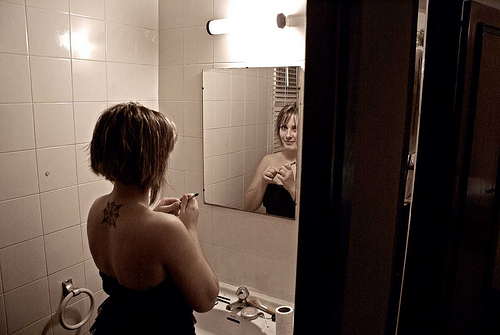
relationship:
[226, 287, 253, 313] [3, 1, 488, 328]
faucet in bathroom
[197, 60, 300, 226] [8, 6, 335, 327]
mirror in bathroom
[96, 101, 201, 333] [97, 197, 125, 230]
lady has tattoo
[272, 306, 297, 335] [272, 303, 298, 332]
tissue has roll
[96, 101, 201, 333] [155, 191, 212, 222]
lady has hands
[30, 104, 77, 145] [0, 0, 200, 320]
tile on wall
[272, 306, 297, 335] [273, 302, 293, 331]
tissue has roll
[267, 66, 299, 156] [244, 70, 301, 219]
window has reflection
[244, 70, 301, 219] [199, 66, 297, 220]
reflection in mirror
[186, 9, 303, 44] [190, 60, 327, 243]
light over mirror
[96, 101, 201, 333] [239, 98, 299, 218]
lady looking at herself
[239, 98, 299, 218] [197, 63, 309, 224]
herself in mirror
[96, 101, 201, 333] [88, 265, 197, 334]
lady wearing dress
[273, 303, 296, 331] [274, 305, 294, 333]
tissue has roll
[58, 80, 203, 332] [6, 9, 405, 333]
lady in bathroom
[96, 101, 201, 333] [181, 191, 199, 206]
lady holding something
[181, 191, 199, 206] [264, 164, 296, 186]
something in hands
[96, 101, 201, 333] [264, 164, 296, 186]
lady has hands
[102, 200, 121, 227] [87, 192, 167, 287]
tattoo on back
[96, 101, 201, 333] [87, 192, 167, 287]
lady has back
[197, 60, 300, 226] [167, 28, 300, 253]
mirror on wall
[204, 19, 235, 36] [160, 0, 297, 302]
light on wall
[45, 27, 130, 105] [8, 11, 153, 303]
tiles on wall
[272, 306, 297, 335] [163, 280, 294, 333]
tissue on sink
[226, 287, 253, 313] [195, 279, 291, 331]
faucet on sink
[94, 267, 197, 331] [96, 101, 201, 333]
dress on lady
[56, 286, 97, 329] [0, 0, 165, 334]
hanger on wall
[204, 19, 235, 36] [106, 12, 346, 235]
light on wall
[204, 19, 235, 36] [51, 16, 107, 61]
light has reflection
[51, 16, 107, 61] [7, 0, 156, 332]
reflection on tile